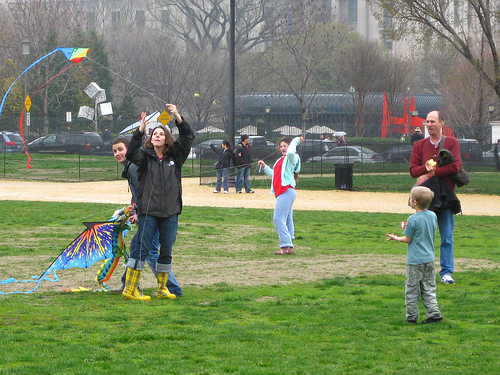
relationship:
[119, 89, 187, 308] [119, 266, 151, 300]
woman wearing boot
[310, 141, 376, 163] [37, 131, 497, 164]
gray car on road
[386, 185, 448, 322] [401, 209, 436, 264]
child wearing shirt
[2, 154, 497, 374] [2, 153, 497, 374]
grass on field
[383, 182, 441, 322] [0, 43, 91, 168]
boy holding kite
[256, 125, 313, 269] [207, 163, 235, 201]
woman wearing jeans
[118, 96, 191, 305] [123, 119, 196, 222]
lady wearing a jacket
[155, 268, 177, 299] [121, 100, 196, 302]
yellow boot on woman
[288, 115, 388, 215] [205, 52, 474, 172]
car in parking lot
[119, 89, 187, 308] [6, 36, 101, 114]
woman flying a kite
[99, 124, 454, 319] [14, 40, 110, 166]
children with kites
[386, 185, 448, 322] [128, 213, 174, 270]
child wearing pants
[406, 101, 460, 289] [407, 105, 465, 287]
man wearing shirt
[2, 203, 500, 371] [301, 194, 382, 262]
grass on ground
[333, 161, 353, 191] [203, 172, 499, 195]
trash bin on grass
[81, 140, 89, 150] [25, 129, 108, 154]
tail light on vehicle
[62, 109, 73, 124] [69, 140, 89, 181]
sign on post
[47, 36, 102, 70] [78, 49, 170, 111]
kite on string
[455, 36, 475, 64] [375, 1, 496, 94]
branch on tree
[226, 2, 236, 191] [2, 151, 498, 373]
pole in park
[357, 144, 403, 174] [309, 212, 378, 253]
fence along grass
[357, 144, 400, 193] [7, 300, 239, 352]
fence along grass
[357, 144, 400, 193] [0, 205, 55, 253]
fence along grass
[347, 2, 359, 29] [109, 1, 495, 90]
window on building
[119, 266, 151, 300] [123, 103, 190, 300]
boot on woman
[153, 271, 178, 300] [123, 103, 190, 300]
boot on woman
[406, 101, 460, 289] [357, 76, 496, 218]
man holding coat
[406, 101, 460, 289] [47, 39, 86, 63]
man holding kite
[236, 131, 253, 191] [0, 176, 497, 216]
people walking on path